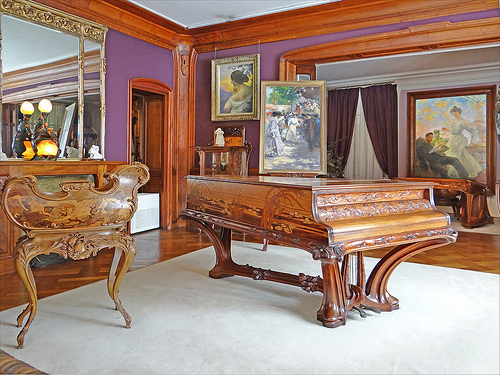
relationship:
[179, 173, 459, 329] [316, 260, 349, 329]
piano has leg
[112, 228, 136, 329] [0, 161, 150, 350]
leg on bottom of furniture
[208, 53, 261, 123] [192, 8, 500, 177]
painting hanging on wall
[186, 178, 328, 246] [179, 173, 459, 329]
artwork on side of piano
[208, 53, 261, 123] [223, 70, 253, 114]
painting has woman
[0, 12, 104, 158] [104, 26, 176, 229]
mirror hanging on wall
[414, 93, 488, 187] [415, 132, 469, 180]
painting has man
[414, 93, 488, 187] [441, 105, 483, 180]
painting has woman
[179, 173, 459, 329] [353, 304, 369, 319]
piano has foot pedal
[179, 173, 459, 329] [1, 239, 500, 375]
piano sitting on rug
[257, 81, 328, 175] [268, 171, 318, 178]
art sitting on easel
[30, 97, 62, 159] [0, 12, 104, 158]
lamp reflect in mirror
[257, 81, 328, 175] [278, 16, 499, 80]
art leaning against door frame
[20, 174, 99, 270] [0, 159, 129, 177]
fireplace has mantle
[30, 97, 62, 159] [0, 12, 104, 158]
lamp reflecting in mirror